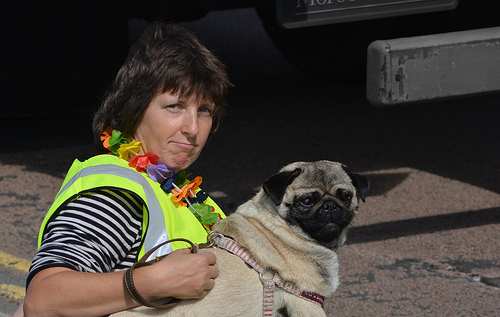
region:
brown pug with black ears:
[106, 160, 370, 314]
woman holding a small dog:
[14, 18, 229, 315]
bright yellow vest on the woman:
[37, 153, 228, 263]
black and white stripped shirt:
[22, 188, 143, 288]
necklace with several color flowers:
[97, 126, 221, 226]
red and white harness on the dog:
[209, 232, 330, 314]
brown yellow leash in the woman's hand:
[122, 235, 209, 310]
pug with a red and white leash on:
[105, 158, 370, 315]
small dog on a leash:
[107, 156, 372, 315]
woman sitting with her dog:
[15, 20, 366, 314]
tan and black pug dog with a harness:
[198, 155, 357, 312]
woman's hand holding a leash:
[123, 234, 226, 311]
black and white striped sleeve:
[28, 178, 142, 276]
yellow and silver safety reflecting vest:
[26, 152, 241, 264]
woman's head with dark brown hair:
[82, 28, 232, 177]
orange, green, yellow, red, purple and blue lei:
[93, 120, 226, 241]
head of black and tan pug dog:
[257, 153, 369, 250]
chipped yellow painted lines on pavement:
[0, 234, 32, 305]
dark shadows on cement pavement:
[352, 154, 493, 242]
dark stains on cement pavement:
[342, 242, 490, 295]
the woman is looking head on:
[98, 38, 222, 182]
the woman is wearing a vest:
[33, 148, 235, 315]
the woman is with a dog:
[32, 53, 362, 309]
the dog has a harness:
[185, 217, 331, 314]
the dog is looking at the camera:
[275, 163, 360, 243]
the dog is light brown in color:
[176, 160, 351, 315]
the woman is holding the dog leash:
[123, 232, 220, 312]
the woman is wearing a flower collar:
[96, 123, 210, 208]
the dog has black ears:
[256, 155, 301, 205]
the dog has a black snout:
[291, 191, 353, 232]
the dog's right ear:
[262, 164, 304, 204]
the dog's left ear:
[337, 164, 374, 200]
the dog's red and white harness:
[209, 231, 328, 315]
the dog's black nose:
[318, 197, 338, 212]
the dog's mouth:
[313, 211, 338, 236]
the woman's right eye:
[162, 100, 183, 112]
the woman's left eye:
[195, 101, 212, 119]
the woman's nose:
[180, 115, 200, 140]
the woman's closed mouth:
[168, 133, 199, 153]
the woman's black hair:
[91, 26, 233, 158]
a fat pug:
[103, 155, 371, 314]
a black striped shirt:
[19, 182, 146, 290]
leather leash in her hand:
[121, 233, 222, 310]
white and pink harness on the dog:
[207, 229, 330, 315]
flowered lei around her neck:
[96, 120, 224, 235]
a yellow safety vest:
[33, 153, 230, 264]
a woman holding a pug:
[18, 15, 370, 314]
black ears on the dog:
[259, 165, 372, 207]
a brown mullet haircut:
[88, 18, 238, 155]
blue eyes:
[163, 95, 214, 117]